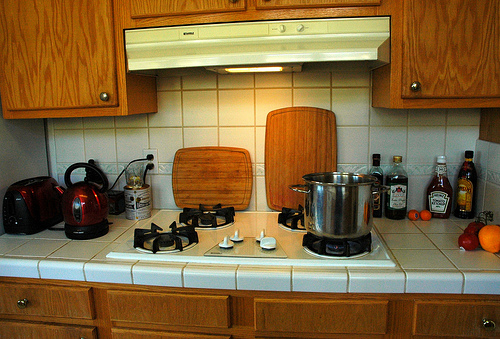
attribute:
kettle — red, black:
[53, 158, 120, 244]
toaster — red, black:
[8, 170, 58, 239]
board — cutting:
[170, 144, 255, 210]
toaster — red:
[10, 159, 75, 238]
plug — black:
[142, 150, 156, 161]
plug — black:
[145, 163, 158, 178]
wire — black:
[107, 156, 147, 191]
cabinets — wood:
[7, 4, 175, 149]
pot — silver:
[282, 171, 382, 249]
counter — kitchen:
[394, 220, 471, 280]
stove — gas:
[123, 179, 401, 273]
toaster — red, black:
[0, 176, 61, 238]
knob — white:
[217, 233, 235, 248]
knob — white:
[231, 224, 244, 242]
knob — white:
[252, 226, 265, 239]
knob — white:
[256, 234, 276, 252]